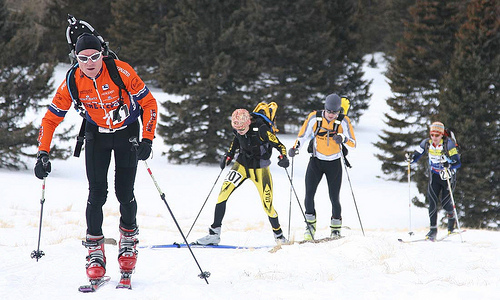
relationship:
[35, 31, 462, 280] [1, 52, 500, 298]
people on snow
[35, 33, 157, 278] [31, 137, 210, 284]
man holding ski poles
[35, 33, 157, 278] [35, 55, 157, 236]
man wearing clothes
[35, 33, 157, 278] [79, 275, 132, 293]
man on skis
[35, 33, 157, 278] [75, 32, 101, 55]
man wearing a hat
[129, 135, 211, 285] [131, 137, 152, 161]
ski pole in left hand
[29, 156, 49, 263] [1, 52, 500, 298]
ski pole in snow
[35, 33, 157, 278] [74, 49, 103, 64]
man wearing goggles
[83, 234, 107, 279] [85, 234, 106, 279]
ski boot on left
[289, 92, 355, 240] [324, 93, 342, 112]
person wearing a hat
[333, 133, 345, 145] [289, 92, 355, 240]
left hand on person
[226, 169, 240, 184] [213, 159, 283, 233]
number on pants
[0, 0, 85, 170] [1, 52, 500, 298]
tree on snow